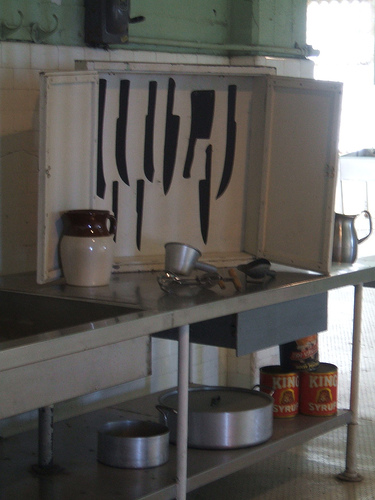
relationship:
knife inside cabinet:
[81, 174, 136, 245] [1, 44, 344, 233]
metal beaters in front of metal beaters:
[153, 244, 224, 300] [153, 244, 224, 300]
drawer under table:
[152, 290, 328, 357] [2, 247, 373, 498]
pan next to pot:
[97, 418, 170, 467] [156, 384, 273, 448]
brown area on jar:
[60, 208, 116, 235] [58, 194, 118, 292]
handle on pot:
[154, 401, 178, 423] [174, 379, 278, 450]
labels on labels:
[268, 347, 338, 415] [257, 331, 338, 420]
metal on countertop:
[0, 203, 375, 500] [0, 247, 372, 375]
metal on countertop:
[327, 203, 374, 266] [0, 247, 372, 375]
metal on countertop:
[158, 240, 219, 276] [0, 247, 372, 375]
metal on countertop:
[153, 271, 230, 291] [0, 247, 372, 375]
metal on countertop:
[147, 378, 283, 450] [0, 247, 372, 375]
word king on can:
[273, 376, 297, 386] [257, 365, 300, 422]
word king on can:
[273, 376, 297, 386] [299, 360, 340, 420]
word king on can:
[310, 376, 336, 385] [276, 325, 321, 371]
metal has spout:
[327, 203, 374, 266] [334, 210, 342, 218]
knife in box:
[195, 143, 212, 244] [28, 53, 346, 292]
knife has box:
[195, 143, 212, 244] [28, 53, 346, 292]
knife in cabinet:
[113, 79, 129, 184] [27, 50, 351, 292]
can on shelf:
[299, 360, 337, 417] [0, 385, 350, 499]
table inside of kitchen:
[2, 247, 373, 498] [6, 2, 374, 475]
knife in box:
[142, 79, 158, 184] [28, 53, 346, 292]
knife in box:
[113, 79, 129, 184] [28, 53, 346, 292]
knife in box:
[162, 77, 179, 195] [28, 53, 346, 292]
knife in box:
[215, 84, 240, 198] [28, 53, 346, 292]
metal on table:
[327, 203, 374, 266] [3, 237, 374, 381]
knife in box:
[97, 77, 110, 205] [28, 53, 346, 292]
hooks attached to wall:
[0, 3, 62, 47] [0, 1, 308, 74]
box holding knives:
[36, 53, 346, 283] [99, 78, 242, 246]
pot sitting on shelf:
[153, 379, 281, 454] [131, 461, 225, 487]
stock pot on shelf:
[96, 419, 169, 466] [4, 412, 175, 497]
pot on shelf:
[154, 231, 242, 296] [54, 261, 361, 316]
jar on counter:
[63, 194, 126, 289] [1, 257, 374, 351]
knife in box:
[215, 84, 240, 198] [36, 53, 346, 283]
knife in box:
[183, 87, 215, 178] [36, 53, 346, 283]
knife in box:
[195, 143, 212, 244] [36, 53, 346, 283]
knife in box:
[113, 79, 129, 184] [36, 53, 346, 283]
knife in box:
[162, 77, 179, 195] [36, 53, 346, 283]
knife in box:
[142, 79, 158, 184] [36, 53, 346, 283]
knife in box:
[135, 177, 143, 252] [36, 53, 346, 283]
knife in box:
[112, 180, 120, 241] [36, 53, 346, 283]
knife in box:
[97, 77, 110, 205] [36, 53, 346, 283]